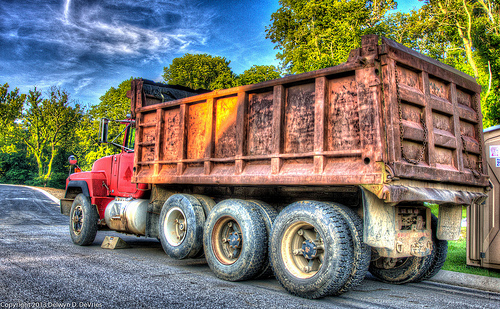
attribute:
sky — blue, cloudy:
[1, 1, 431, 131]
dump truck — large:
[60, 33, 490, 300]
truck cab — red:
[65, 121, 147, 218]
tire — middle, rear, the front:
[68, 193, 97, 245]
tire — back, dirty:
[268, 200, 353, 299]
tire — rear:
[203, 197, 267, 283]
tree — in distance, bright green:
[17, 89, 82, 183]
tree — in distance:
[0, 83, 27, 174]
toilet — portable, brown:
[467, 124, 500, 272]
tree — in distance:
[165, 53, 232, 91]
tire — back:
[324, 200, 372, 297]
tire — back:
[368, 233, 438, 281]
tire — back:
[413, 213, 448, 283]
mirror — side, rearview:
[99, 118, 110, 145]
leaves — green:
[239, 65, 281, 87]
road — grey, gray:
[1, 185, 499, 307]